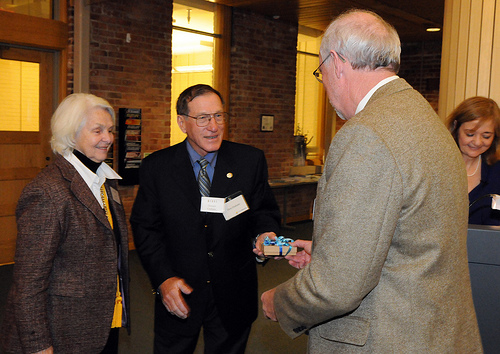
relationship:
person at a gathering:
[128, 83, 285, 354] [10, 8, 499, 353]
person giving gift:
[128, 83, 285, 354] [260, 235, 299, 259]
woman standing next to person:
[5, 92, 132, 354] [128, 83, 285, 354]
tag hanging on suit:
[200, 194, 227, 216] [128, 138, 283, 353]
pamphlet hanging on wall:
[125, 114, 142, 121] [69, 0, 384, 251]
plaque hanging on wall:
[258, 112, 277, 134] [69, 0, 384, 251]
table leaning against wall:
[266, 172, 320, 231] [69, 0, 384, 251]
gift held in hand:
[260, 235, 299, 259] [251, 230, 277, 259]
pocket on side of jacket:
[317, 314, 372, 353] [275, 76, 485, 353]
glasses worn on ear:
[312, 50, 346, 83] [330, 51, 345, 80]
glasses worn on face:
[176, 111, 232, 128] [188, 92, 229, 152]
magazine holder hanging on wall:
[115, 105, 145, 187] [69, 0, 384, 251]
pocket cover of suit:
[235, 255, 255, 274] [128, 138, 283, 353]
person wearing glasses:
[128, 83, 285, 354] [176, 111, 232, 128]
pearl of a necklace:
[470, 174, 474, 178] [461, 151, 483, 178]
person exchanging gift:
[128, 83, 285, 354] [260, 235, 299, 259]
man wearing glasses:
[258, 8, 487, 353] [312, 50, 346, 83]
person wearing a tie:
[128, 83, 285, 354] [195, 156, 213, 198]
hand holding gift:
[251, 230, 277, 259] [260, 235, 299, 259]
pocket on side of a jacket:
[317, 314, 372, 353] [275, 76, 485, 353]